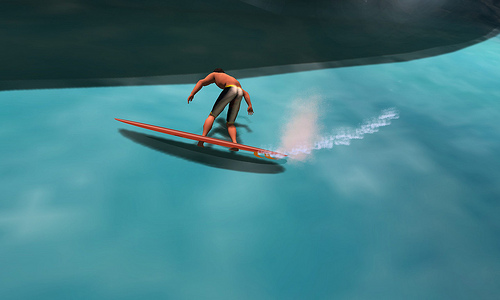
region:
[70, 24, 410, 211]
Man on a surfboard.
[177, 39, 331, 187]
Man wearing board shorts.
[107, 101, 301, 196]
Surfboard under the man.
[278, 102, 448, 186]
Spray in the water.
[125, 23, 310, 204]
Computer generated man.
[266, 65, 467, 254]
Computer generated water.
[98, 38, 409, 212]
Computer generated man on a skateboard.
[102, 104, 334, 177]
Orange computer generated surfboard.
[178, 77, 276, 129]
Black and gray board shorts.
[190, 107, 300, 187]
Legs on the surfer.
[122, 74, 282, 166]
a man on a red surfboard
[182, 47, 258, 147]
a man wearing black board shorts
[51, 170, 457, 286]
clear blue water of the wave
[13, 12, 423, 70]
dark blue water of the ocean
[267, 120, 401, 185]
white ocean foam and spray coming from the surfboard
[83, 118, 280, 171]
a red surboard on the ocean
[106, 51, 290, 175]
a computer generated man riding a surfboard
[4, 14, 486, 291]
a computer generated scene of a man on a surfboard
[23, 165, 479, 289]
cloudy blue computer generated water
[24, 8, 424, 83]
dark blue computer generated water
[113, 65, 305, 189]
guy wake boarding in water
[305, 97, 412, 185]
small water wave in blue water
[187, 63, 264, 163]
guy in swimming shorts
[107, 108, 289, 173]
red wake board in water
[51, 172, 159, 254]
blue calm water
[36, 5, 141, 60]
dark blue calm water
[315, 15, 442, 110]
blue and dark blue water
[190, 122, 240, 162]
two legs of man on wake board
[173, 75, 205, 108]
one hand of man in water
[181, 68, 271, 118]
man with back arched in water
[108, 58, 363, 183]
a man is using surfboard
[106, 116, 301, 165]
a surfboard with brown colour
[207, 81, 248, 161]
a man wearing shorts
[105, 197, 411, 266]
a clear blue colour water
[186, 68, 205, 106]
a person hand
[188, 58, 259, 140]
a man is crouching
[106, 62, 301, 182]
a person with the surfboard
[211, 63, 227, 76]
a head of the person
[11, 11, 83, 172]
a skyblue and a dark colour water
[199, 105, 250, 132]
knee of the person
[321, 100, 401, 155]
Wake from surfboard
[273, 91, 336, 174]
Spray from surfboard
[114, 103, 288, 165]
Riding a red surfboard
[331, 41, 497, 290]
Different shades of blue water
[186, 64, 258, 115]
Surfer has a tan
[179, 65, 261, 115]
Arms out for balance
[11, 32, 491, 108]
Water the water ends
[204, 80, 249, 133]
Gray and black shorts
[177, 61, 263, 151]
Surfer is bent over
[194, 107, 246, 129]
Shorts just above the knee